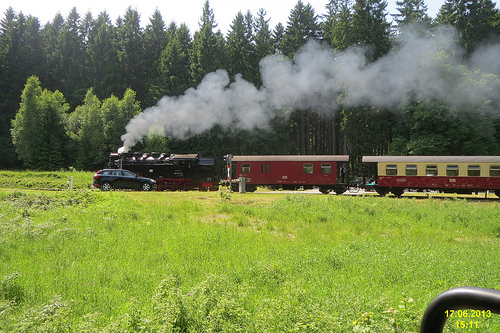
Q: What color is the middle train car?
A: Red.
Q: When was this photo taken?
A: Morning.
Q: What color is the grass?
A: Green.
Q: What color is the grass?
A: Green.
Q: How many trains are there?
A: One.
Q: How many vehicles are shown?
A: Two.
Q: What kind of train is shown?
A: Steam engine.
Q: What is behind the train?
A: Trees.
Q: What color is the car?
A: Black.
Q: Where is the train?
A: On the tracks.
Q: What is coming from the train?
A: Steam.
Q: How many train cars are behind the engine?
A: Two.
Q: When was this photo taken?
A: 17.06.2013.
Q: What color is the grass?
A: Green.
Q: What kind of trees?
A: Evergreen.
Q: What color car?
A: Black.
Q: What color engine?
A: Black.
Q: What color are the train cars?
A: Red.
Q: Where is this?
A: Country.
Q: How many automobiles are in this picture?
A: One.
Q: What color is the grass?
A: Green.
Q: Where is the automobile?
A: Beside the train.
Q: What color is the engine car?
A: Black.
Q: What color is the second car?
A: Red.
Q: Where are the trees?
A: Behind the train.